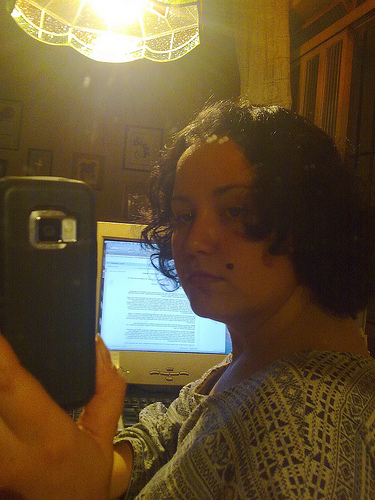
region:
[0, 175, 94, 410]
black cellphone on woman's hand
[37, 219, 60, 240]
camera on the cellphone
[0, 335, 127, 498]
hand of woman holding a cellphone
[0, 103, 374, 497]
woman holding a cellphone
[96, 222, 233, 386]
computer screen turned on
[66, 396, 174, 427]
black keyboard of a computer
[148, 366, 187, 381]
buttons on the computer screen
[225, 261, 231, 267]
black moll on woman's face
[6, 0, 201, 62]
lamp above the woman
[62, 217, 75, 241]
flash next to the cellphone's camera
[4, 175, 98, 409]
a black camera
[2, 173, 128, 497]
woman holding a black camera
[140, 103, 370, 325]
woman with brown curly hair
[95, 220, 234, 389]
a white computer monitor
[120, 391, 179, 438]
a black keyboard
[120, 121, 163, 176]
a framed picture on a wall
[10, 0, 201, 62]
a lamp overhead a woman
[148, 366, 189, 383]
a bunch of buttons on a computer monitor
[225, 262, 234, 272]
a mole on woman's face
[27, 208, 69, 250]
silver eye of a camera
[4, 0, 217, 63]
A bright ceiling light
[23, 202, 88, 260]
A camera lens on a phone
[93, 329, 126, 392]
A thumb with a clear nail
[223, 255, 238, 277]
A mole on the cheek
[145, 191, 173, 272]
Black curly, wavy hair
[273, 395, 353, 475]
A white top with a pattern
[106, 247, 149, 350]
An open computer screen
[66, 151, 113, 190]
A picture on the wall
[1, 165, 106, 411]
The back of a mobile device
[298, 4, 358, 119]
A wooden door and frame in the background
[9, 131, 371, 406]
a woman holding a pohne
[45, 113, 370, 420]
a woman holding a black phone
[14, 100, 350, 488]
a woman holding a cell phone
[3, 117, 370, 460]
a woman holding a black cell phone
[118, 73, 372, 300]
a woman with curly hair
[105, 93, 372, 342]
a woman with black curly hair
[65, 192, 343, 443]
a computer monitor turned on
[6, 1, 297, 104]
a light that is turned on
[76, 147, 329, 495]
a woman sitting inside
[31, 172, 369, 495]
a woman sitting in front of computer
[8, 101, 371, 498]
woman with the black curly hair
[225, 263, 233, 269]
mole on the woman's face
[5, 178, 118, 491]
cell phone in the woman's hand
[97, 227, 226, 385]
computer monitor turned on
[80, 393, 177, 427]
black computer keyboard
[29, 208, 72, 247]
camera and flash on the phone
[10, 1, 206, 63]
lamp overhead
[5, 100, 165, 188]
framed pictures on the wall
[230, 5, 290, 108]
a curtain behind the woman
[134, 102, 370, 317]
curly black hair